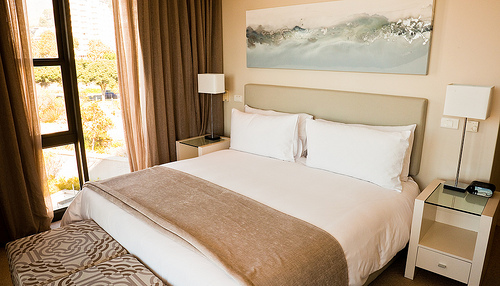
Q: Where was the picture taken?
A: A hotel.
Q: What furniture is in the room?
A: Bed and lamp tables.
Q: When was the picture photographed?
A: Daytime.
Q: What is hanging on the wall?
A: A painting.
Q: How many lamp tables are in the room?
A: Two.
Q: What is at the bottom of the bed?
A: A blanket.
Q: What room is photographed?
A: Bedroom.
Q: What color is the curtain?
A: Brown.